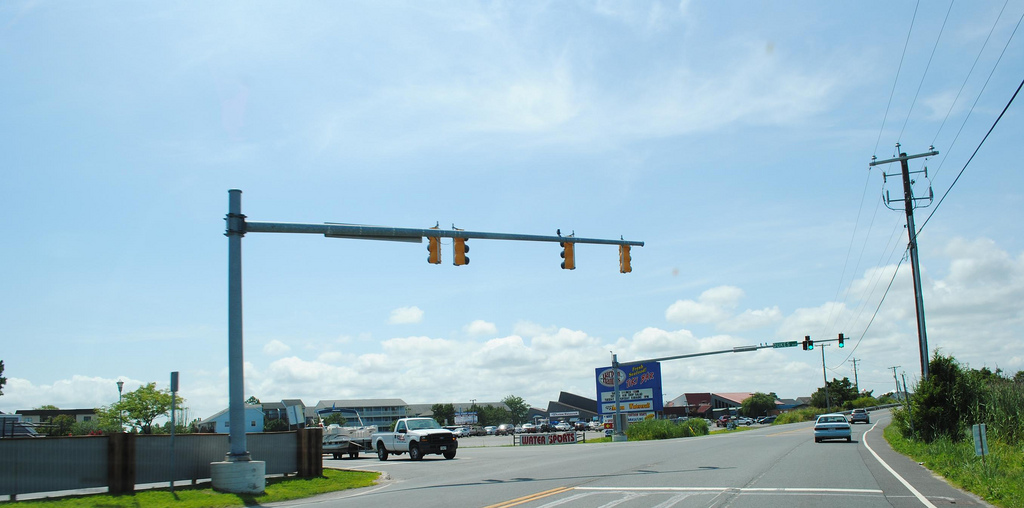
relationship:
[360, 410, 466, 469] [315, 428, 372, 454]
truck towing boat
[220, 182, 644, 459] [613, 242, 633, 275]
pole holding light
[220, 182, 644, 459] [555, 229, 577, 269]
pole holding light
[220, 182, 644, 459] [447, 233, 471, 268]
pole holding light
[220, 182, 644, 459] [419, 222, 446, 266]
pole holding light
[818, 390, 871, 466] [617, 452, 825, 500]
cars on road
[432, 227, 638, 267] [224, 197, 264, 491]
signal on pole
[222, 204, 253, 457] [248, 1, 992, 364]
post with wires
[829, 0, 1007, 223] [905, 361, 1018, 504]
wires over plants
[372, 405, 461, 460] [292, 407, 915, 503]
truck entering road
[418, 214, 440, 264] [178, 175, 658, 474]
signal on pole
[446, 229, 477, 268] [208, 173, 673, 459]
signal wearing pole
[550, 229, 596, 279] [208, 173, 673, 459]
signal on pole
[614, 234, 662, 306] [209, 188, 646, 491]
signal on pole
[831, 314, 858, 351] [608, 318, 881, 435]
signal on pole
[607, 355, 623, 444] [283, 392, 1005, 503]
pole by street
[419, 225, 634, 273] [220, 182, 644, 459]
lights on pole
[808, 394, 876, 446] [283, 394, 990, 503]
cars on road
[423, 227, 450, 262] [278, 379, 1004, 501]
stoplights hanging over road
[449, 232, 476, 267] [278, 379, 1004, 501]
stoplights hanging over road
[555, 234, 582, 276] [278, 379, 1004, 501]
stoplights hanging over road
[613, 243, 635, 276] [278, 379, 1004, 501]
stoplights hanging over road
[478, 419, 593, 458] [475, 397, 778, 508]
rectangular sign on road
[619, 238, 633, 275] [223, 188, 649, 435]
light on pole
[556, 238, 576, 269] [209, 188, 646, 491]
light on pole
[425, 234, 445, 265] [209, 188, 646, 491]
light on pole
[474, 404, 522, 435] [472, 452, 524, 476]
car on road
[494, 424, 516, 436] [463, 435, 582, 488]
car on road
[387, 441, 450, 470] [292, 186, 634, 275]
truck at light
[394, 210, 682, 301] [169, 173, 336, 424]
traffic lights on pole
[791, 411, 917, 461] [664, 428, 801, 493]
cars driving down road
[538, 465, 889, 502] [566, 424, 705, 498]
line across street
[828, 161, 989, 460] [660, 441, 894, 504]
pole on side road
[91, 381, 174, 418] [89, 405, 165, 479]
tree behind fence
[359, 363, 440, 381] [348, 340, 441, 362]
clouds in sky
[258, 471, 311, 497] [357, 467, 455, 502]
grass on side of road